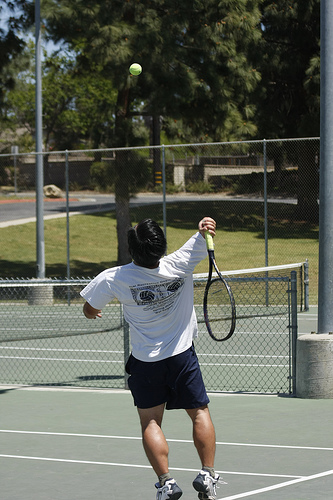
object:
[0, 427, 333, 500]
lines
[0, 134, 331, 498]
court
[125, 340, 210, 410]
blue shorts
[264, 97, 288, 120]
ground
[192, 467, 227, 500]
tennis shoe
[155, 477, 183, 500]
tennis shoe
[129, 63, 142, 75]
ball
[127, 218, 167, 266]
hair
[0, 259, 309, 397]
fence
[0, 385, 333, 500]
tennis court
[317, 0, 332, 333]
pole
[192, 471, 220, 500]
foot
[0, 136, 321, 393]
fence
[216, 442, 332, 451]
line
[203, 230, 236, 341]
racket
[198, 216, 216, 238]
hand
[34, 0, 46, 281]
light pole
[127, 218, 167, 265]
head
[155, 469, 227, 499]
tennis shoes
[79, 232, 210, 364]
shirt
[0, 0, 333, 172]
air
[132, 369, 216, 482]
legs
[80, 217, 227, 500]
man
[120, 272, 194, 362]
back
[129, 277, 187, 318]
image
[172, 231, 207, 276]
arm